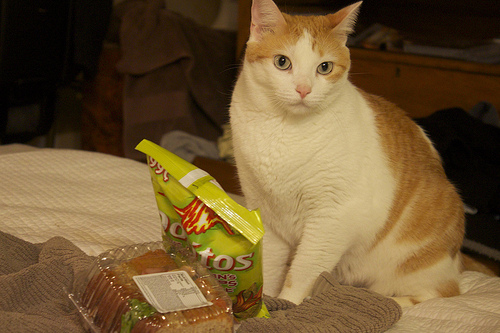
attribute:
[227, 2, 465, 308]
cat — brown, white, here, orange-colored, cream-colored, orange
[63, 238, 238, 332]
box — plastic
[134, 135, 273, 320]
bag — green, yellow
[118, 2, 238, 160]
towel — light brown, tan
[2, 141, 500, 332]
bed spread — white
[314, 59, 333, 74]
right eye — green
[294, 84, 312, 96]
nose — pink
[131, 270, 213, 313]
sticker — white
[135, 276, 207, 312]
writing — black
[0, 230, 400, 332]
towel — brown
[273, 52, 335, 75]
eyes — green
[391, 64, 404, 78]
key hole — small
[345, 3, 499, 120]
chest — brown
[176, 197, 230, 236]
flame — orange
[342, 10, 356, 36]
hair — white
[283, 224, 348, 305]
leg — white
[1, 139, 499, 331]
blanket — white